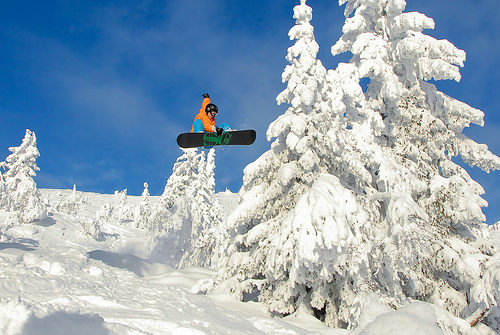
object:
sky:
[1, 4, 500, 228]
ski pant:
[188, 117, 222, 130]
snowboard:
[177, 127, 258, 150]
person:
[186, 92, 233, 149]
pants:
[191, 118, 230, 135]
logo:
[198, 128, 232, 148]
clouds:
[0, 2, 500, 228]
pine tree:
[221, 4, 496, 319]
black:
[176, 129, 254, 147]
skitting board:
[177, 130, 255, 149]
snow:
[238, 0, 498, 255]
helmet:
[204, 101, 219, 116]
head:
[206, 103, 217, 118]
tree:
[337, 2, 494, 327]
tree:
[219, 3, 348, 316]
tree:
[155, 151, 224, 267]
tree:
[133, 176, 155, 233]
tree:
[8, 128, 46, 224]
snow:
[13, 250, 165, 326]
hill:
[17, 183, 262, 325]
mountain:
[6, 119, 496, 329]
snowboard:
[145, 119, 310, 159]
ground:
[1, 192, 491, 333]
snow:
[1, 194, 496, 333]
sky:
[48, 38, 206, 147]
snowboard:
[176, 123, 274, 157]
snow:
[59, 222, 233, 332]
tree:
[317, 62, 443, 266]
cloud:
[3, 82, 13, 101]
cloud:
[4, 120, 20, 141]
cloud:
[152, 174, 165, 191]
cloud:
[92, 20, 176, 80]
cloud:
[470, 11, 477, 22]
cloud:
[69, 160, 88, 173]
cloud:
[95, 157, 109, 165]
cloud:
[52, 75, 152, 145]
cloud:
[60, 20, 81, 38]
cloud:
[310, 3, 344, 61]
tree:
[228, 5, 417, 323]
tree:
[326, 4, 498, 316]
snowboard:
[172, 127, 257, 152]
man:
[190, 93, 223, 136]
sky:
[4, 0, 498, 218]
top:
[193, 95, 220, 127]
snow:
[275, 41, 420, 266]